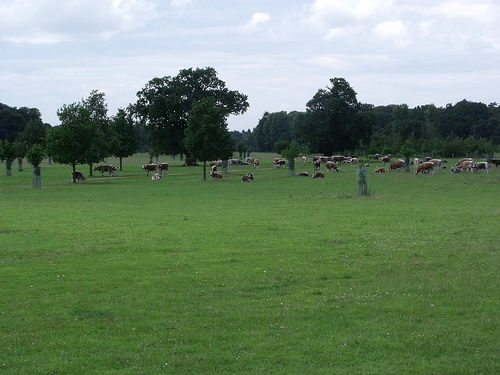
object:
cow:
[140, 162, 158, 178]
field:
[2, 151, 500, 373]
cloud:
[244, 1, 388, 25]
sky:
[1, 0, 499, 135]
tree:
[183, 97, 237, 181]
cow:
[93, 164, 119, 177]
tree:
[104, 108, 143, 172]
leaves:
[116, 126, 130, 137]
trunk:
[118, 157, 123, 172]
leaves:
[183, 95, 197, 107]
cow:
[207, 169, 227, 179]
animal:
[311, 170, 326, 178]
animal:
[324, 163, 343, 172]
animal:
[239, 170, 256, 184]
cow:
[70, 170, 90, 183]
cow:
[389, 159, 406, 172]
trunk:
[203, 158, 208, 183]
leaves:
[71, 136, 85, 145]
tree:
[46, 88, 120, 180]